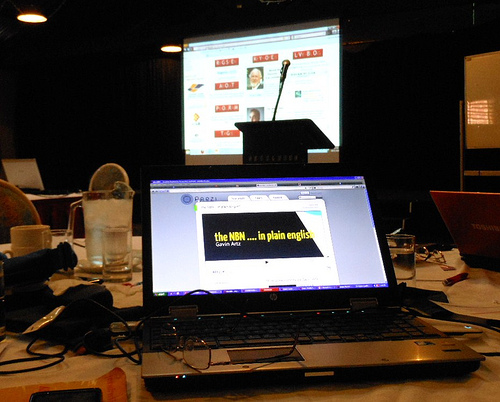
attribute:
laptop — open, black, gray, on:
[135, 158, 486, 390]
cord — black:
[3, 296, 145, 377]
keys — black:
[150, 312, 430, 347]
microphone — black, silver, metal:
[277, 59, 293, 88]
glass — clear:
[101, 223, 132, 281]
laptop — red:
[430, 188, 498, 272]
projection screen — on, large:
[178, 17, 345, 169]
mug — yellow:
[11, 222, 49, 253]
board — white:
[462, 48, 500, 149]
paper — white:
[418, 265, 499, 310]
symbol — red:
[212, 57, 242, 67]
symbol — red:
[214, 80, 238, 91]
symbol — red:
[211, 101, 240, 112]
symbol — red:
[214, 128, 241, 138]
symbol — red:
[251, 51, 280, 62]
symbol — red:
[293, 47, 325, 61]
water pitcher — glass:
[63, 182, 136, 268]